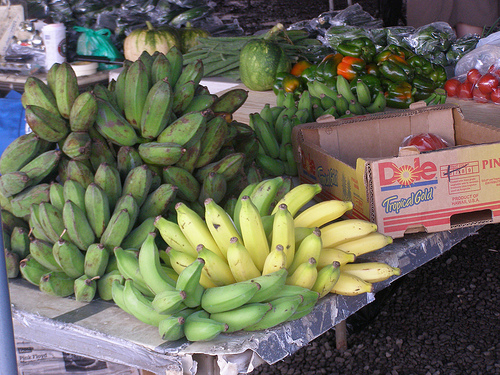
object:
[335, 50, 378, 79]
peppers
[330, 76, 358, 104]
bananas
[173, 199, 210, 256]
bananas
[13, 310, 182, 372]
edge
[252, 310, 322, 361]
edge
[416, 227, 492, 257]
edge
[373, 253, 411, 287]
edge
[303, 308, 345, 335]
edge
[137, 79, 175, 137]
bananas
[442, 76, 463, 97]
red tomatoes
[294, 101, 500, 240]
box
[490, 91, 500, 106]
tomatoes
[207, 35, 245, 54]
vegetables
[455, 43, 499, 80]
donuts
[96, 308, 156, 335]
top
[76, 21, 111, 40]
ribbon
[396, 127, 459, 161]
pepper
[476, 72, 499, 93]
tomato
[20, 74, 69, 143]
bananas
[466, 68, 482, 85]
tomato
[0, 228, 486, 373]
stand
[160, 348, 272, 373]
corner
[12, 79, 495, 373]
table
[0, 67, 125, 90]
table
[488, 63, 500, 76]
tomatoes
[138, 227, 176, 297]
bananas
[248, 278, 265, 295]
tip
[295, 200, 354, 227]
banana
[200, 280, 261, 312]
banana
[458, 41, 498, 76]
bag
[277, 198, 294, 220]
tip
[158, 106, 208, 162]
bananas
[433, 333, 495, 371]
gravel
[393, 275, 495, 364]
ground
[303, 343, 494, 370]
ground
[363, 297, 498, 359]
floor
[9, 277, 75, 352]
table top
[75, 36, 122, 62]
plastic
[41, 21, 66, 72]
mug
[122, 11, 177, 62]
calabas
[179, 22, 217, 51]
pumpkin squash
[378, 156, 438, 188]
dole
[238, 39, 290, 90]
watermelon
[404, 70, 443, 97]
peppers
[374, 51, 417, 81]
bell pepper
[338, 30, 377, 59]
bell pepper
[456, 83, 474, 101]
tomato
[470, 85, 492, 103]
tomato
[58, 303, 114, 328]
part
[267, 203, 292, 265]
banana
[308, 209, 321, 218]
part